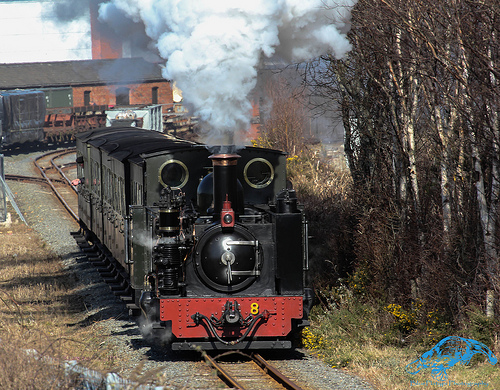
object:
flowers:
[331, 246, 386, 312]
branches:
[291, 47, 387, 121]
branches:
[437, 229, 482, 309]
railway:
[33, 144, 309, 390]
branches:
[389, 182, 444, 314]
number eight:
[248, 300, 260, 316]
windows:
[77, 156, 124, 216]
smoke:
[37, 0, 359, 153]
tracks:
[32, 147, 78, 222]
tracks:
[208, 359, 291, 388]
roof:
[0, 56, 175, 90]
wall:
[236, 79, 300, 139]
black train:
[70, 126, 314, 348]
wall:
[89, 87, 110, 108]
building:
[0, 3, 179, 154]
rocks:
[308, 356, 327, 387]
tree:
[285, 0, 496, 350]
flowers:
[384, 297, 435, 328]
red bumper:
[159, 293, 303, 336]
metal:
[195, 351, 238, 388]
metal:
[248, 346, 303, 388]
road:
[277, 346, 319, 388]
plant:
[365, 205, 428, 300]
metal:
[220, 237, 260, 252]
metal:
[224, 298, 242, 323]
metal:
[157, 201, 178, 232]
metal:
[211, 152, 246, 202]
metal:
[278, 189, 305, 294]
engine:
[73, 124, 314, 356]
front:
[143, 148, 313, 360]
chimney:
[209, 142, 239, 220]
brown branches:
[288, 0, 500, 214]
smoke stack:
[212, 149, 243, 230]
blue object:
[404, 334, 498, 388]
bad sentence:
[187, 258, 297, 319]